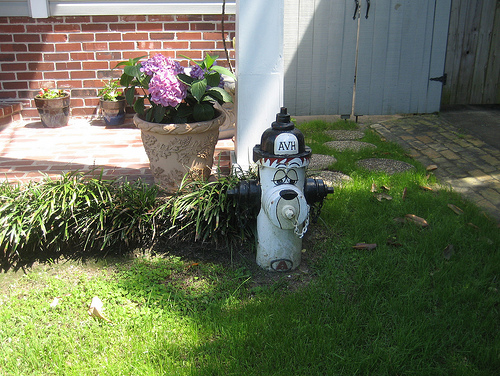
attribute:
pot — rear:
[25, 86, 73, 128]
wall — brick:
[19, 21, 223, 116]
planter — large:
[133, 112, 225, 192]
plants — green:
[10, 180, 230, 245]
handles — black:
[348, 0, 374, 25]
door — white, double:
[290, 0, 454, 120]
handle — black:
[351, 0, 360, 21]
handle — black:
[360, 0, 374, 16]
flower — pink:
[137, 48, 179, 118]